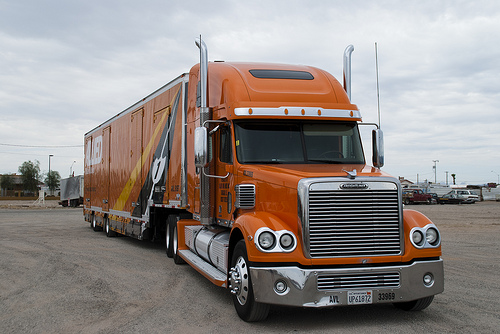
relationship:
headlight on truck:
[256, 226, 277, 248] [52, 37, 457, 327]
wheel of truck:
[98, 208, 113, 237] [52, 37, 457, 327]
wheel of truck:
[87, 208, 100, 228] [75, 34, 447, 323]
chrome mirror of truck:
[192, 117, 207, 174] [86, 80, 417, 292]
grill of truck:
[305, 176, 405, 257] [75, 34, 447, 323]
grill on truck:
[305, 176, 405, 257] [75, 34, 447, 323]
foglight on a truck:
[423, 270, 434, 285] [52, 37, 457, 327]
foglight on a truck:
[273, 280, 287, 292] [52, 37, 457, 327]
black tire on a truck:
[227, 235, 269, 325] [52, 37, 457, 327]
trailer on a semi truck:
[71, 62, 202, 251] [182, 37, 443, 320]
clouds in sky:
[24, 12, 80, 49] [387, 17, 487, 160]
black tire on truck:
[227, 235, 269, 325] [134, 74, 494, 294]